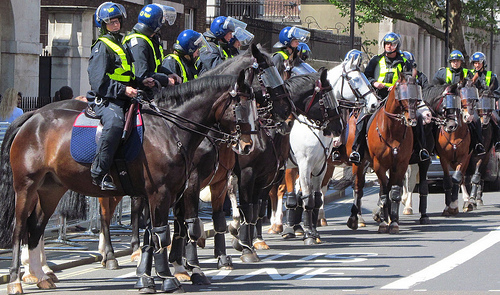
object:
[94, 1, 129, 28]
helmet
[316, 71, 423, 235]
horse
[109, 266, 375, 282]
paint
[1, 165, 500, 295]
street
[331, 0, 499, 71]
tree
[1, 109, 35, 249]
tail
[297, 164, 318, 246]
leg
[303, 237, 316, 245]
hoof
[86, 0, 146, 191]
man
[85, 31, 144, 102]
jacket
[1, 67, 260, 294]
horse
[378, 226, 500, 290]
line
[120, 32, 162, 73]
stripe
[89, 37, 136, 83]
vest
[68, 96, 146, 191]
saddle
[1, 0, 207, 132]
building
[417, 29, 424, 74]
columns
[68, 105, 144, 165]
padding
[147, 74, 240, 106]
mane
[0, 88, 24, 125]
person